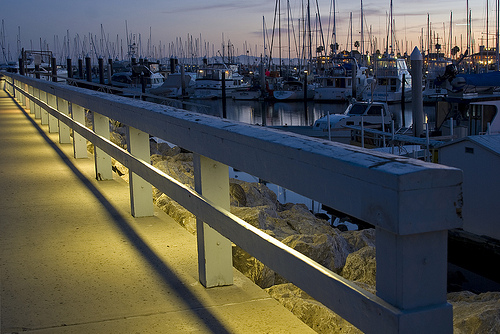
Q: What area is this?
A: Marina.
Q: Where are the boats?
A: Water.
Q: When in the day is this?
A: Late afternoon.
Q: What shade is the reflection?
A: Yellow.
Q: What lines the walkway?
A: Fence.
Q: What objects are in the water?
A: Boats.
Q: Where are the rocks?
A: Shoreline.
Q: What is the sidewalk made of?
A: Concrete.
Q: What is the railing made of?
A: Wood.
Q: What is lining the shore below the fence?
A: Rocks.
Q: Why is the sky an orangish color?
A: Sun is setting.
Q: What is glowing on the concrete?
A: Light.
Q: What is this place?
A: Marina.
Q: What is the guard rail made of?
A: Wood.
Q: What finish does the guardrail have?
A: White paint.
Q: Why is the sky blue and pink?
A: Sunset.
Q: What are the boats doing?
A: They're docked.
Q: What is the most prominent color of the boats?
A: White.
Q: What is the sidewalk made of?
A: Cement.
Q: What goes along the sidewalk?
A: Railing.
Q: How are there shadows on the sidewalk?
A: Lights.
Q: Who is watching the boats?
A: Nobody is watching the boats.